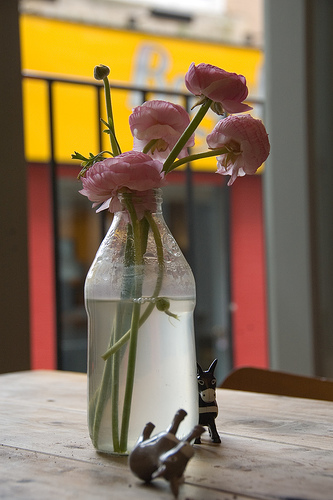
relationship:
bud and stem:
[91, 63, 112, 81] [92, 68, 128, 157]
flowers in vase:
[78, 64, 270, 207] [86, 182, 195, 456]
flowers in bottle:
[78, 64, 270, 207] [86, 182, 195, 456]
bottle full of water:
[86, 182, 195, 456] [91, 297, 198, 450]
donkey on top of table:
[195, 358, 221, 444] [4, 369, 331, 499]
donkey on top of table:
[133, 410, 208, 491] [4, 369, 331, 499]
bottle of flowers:
[86, 182, 195, 456] [78, 64, 270, 207]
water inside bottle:
[91, 297, 198, 450] [86, 182, 195, 456]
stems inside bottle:
[99, 215, 163, 451] [86, 182, 195, 456]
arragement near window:
[74, 61, 274, 452] [19, 2, 263, 373]